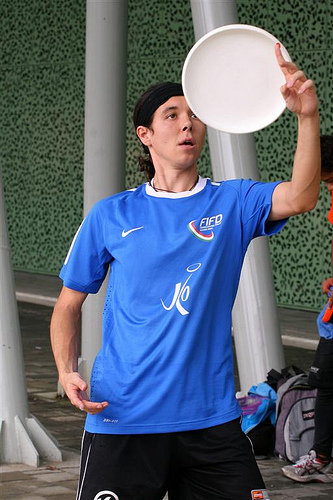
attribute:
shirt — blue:
[58, 179, 286, 436]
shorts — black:
[77, 420, 268, 500]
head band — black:
[133, 84, 189, 130]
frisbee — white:
[181, 23, 293, 137]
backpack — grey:
[277, 366, 320, 465]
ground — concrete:
[5, 304, 330, 499]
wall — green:
[0, 0, 331, 315]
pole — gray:
[56, 1, 127, 401]